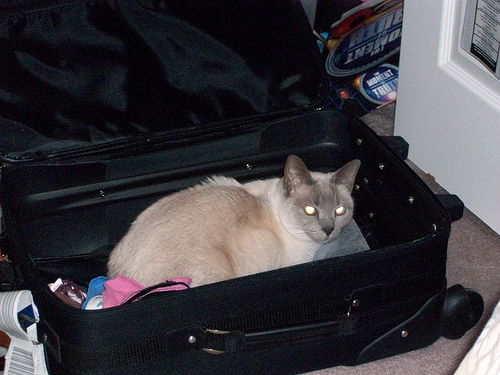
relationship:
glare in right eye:
[304, 203, 347, 215] [302, 202, 318, 217]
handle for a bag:
[202, 304, 357, 352] [2, 2, 478, 368]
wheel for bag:
[446, 282, 481, 342] [2, 2, 478, 368]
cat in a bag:
[94, 154, 370, 291] [2, 2, 478, 368]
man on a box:
[333, 86, 364, 116] [312, 1, 405, 118]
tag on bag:
[2, 287, 55, 374] [2, 2, 478, 368]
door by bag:
[386, 2, 500, 236] [2, 2, 478, 368]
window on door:
[456, 1, 499, 93] [386, 2, 500, 236]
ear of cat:
[282, 150, 316, 189] [94, 154, 370, 291]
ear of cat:
[337, 159, 364, 193] [94, 154, 370, 291]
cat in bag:
[94, 154, 370, 291] [2, 2, 478, 368]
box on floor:
[312, 1, 405, 118] [278, 94, 499, 375]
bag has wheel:
[2, 2, 478, 368] [446, 282, 481, 342]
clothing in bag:
[40, 198, 373, 317] [2, 2, 478, 368]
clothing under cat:
[40, 198, 373, 317] [94, 154, 370, 291]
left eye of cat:
[334, 201, 348, 218] [94, 154, 370, 291]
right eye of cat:
[304, 202, 318, 219] [94, 154, 370, 291]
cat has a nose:
[94, 154, 370, 291] [325, 226, 333, 234]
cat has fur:
[94, 154, 370, 291] [113, 160, 360, 289]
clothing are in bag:
[99, 272, 191, 315] [2, 2, 478, 368]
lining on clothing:
[120, 280, 191, 304] [99, 272, 191, 315]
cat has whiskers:
[94, 154, 370, 291] [288, 212, 354, 240]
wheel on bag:
[446, 282, 481, 342] [2, 2, 478, 368]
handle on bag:
[202, 304, 357, 352] [2, 2, 478, 368]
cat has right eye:
[94, 154, 370, 291] [302, 202, 318, 217]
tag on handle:
[2, 287, 55, 374] [18, 302, 61, 360]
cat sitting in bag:
[94, 154, 370, 291] [2, 2, 478, 368]